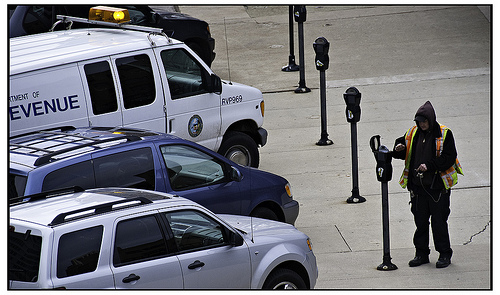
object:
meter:
[369, 134, 400, 271]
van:
[8, 126, 299, 227]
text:
[8, 90, 79, 120]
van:
[8, 6, 269, 170]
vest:
[398, 124, 465, 189]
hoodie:
[391, 100, 460, 195]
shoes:
[433, 253, 453, 268]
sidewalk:
[150, 5, 492, 290]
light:
[88, 6, 132, 23]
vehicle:
[9, 186, 319, 292]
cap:
[413, 113, 427, 124]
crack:
[462, 218, 492, 246]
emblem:
[187, 114, 203, 138]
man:
[391, 99, 464, 268]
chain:
[420, 176, 445, 205]